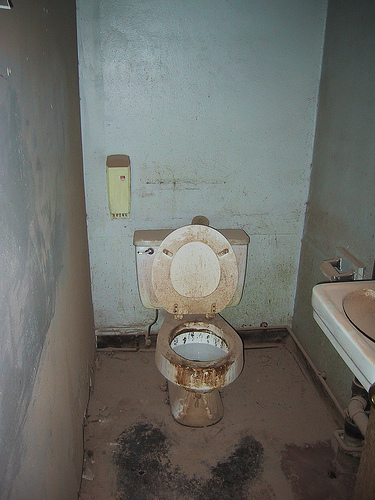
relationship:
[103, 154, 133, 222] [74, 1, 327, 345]
air freshener on wall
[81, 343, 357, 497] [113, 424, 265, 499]
bathroom floor has spot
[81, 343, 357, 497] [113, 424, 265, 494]
bathroom floor has spot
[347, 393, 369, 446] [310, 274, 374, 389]
pipes under sink